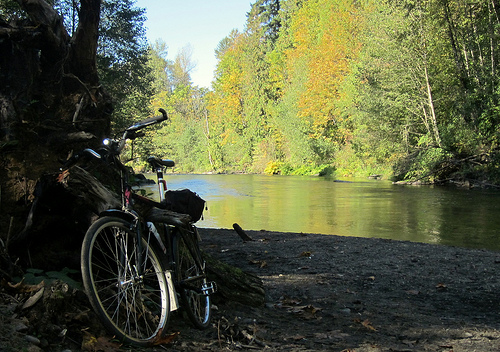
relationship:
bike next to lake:
[64, 106, 222, 344] [136, 168, 499, 254]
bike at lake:
[64, 106, 222, 344] [136, 168, 499, 254]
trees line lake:
[0, 0, 500, 190] [136, 168, 499, 254]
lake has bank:
[136, 168, 499, 254] [84, 224, 500, 351]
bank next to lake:
[84, 224, 500, 351] [136, 168, 499, 254]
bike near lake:
[64, 106, 222, 344] [136, 168, 499, 254]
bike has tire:
[64, 106, 222, 344] [172, 227, 213, 330]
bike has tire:
[64, 106, 222, 344] [80, 213, 173, 348]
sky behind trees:
[54, 1, 281, 96] [0, 0, 500, 190]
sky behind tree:
[54, 1, 281, 96] [209, 27, 264, 177]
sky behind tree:
[54, 1, 281, 96] [264, 3, 302, 97]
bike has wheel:
[64, 106, 222, 344] [75, 211, 176, 347]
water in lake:
[128, 171, 500, 254] [136, 168, 499, 254]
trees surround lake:
[0, 0, 500, 190] [136, 168, 499, 254]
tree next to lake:
[445, 1, 499, 138] [136, 168, 499, 254]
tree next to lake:
[341, 0, 456, 168] [136, 168, 499, 254]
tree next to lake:
[299, 1, 374, 180] [136, 168, 499, 254]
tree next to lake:
[264, 3, 302, 97] [136, 168, 499, 254]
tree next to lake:
[209, 27, 264, 177] [136, 168, 499, 254]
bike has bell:
[64, 106, 222, 344] [100, 136, 111, 151]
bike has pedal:
[64, 106, 222, 344] [201, 279, 220, 297]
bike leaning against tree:
[64, 106, 222, 344] [3, 1, 116, 135]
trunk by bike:
[49, 161, 118, 211] [64, 106, 222, 344]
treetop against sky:
[213, 28, 244, 62] [54, 1, 281, 96]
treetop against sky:
[169, 51, 195, 82] [54, 1, 281, 96]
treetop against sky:
[144, 43, 167, 68] [54, 1, 281, 96]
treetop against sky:
[195, 82, 217, 104] [54, 1, 281, 96]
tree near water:
[341, 0, 456, 168] [128, 171, 500, 254]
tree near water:
[445, 1, 499, 138] [128, 171, 500, 254]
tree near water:
[264, 3, 302, 97] [128, 171, 500, 254]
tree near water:
[209, 27, 264, 177] [128, 171, 500, 254]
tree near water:
[3, 1, 116, 135] [128, 171, 500, 254]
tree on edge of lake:
[341, 0, 456, 168] [136, 168, 499, 254]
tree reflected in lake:
[299, 1, 374, 180] [136, 168, 499, 254]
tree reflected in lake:
[264, 3, 302, 97] [136, 168, 499, 254]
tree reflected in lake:
[341, 0, 456, 168] [136, 168, 499, 254]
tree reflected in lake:
[445, 1, 499, 138] [136, 168, 499, 254]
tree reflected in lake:
[209, 27, 264, 177] [136, 168, 499, 254]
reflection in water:
[208, 174, 409, 237] [128, 171, 500, 254]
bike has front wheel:
[64, 106, 222, 344] [80, 213, 173, 348]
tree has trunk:
[3, 1, 116, 135] [63, 2, 102, 78]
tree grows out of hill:
[3, 1, 116, 135] [4, 98, 187, 276]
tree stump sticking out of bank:
[231, 221, 255, 245] [84, 224, 500, 351]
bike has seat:
[64, 106, 222, 344] [146, 154, 178, 175]